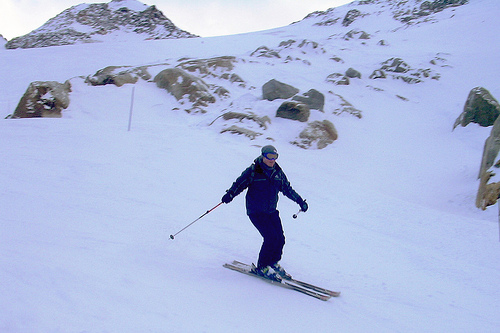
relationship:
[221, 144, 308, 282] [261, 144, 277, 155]
person wearing hat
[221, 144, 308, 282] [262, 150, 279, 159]
person wearing goggles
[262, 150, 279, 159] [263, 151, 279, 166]
goggles on face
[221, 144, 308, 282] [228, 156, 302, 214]
person wearing coat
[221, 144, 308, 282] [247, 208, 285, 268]
person wearing pants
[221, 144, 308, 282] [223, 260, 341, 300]
person wearing skis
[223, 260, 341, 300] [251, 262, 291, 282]
skis on feet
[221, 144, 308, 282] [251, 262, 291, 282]
person wearing boots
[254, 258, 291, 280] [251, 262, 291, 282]
boots on boots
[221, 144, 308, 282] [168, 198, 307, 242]
person holding ski poles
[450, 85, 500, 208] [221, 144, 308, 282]
rocks to right of person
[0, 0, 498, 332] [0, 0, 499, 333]
ground covered in snow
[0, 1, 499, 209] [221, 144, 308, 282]
rocks behind person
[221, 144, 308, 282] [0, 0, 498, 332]
person on ground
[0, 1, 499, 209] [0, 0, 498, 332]
rocks on ground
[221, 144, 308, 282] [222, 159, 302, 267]
person has clothes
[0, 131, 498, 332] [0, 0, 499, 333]
lines in snow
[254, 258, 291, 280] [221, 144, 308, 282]
boots on person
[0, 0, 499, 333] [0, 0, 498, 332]
snow on ground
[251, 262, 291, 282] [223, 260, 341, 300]
feet on skis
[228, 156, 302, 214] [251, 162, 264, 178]
coat has patch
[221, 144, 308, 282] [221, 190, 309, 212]
person wearing gloves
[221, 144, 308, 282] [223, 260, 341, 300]
person on skis